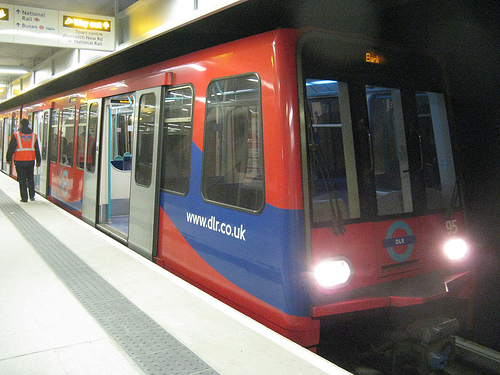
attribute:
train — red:
[8, 14, 473, 354]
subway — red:
[6, 45, 478, 339]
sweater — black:
[1, 122, 43, 169]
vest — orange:
[9, 126, 39, 163]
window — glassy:
[294, 60, 363, 231]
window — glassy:
[409, 85, 469, 210]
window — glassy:
[202, 65, 266, 215]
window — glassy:
[156, 79, 198, 196]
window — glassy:
[131, 87, 159, 193]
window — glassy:
[72, 95, 92, 171]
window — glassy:
[55, 99, 80, 169]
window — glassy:
[41, 100, 58, 160]